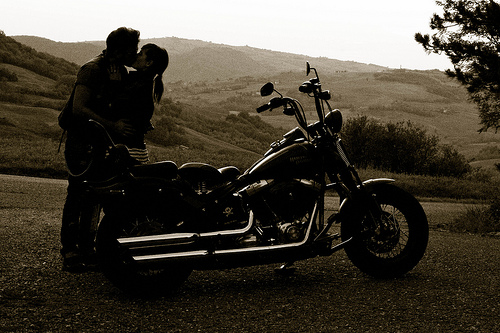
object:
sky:
[0, 0, 499, 72]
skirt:
[103, 141, 154, 169]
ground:
[0, 174, 499, 332]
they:
[58, 26, 170, 273]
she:
[93, 43, 168, 164]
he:
[60, 26, 139, 273]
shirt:
[103, 76, 155, 165]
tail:
[124, 147, 152, 166]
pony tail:
[149, 44, 170, 108]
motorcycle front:
[318, 64, 429, 279]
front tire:
[342, 181, 430, 279]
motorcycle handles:
[298, 77, 323, 92]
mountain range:
[0, 34, 392, 85]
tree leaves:
[415, 32, 427, 44]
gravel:
[276, 311, 283, 317]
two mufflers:
[118, 202, 319, 263]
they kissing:
[56, 26, 170, 271]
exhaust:
[116, 208, 256, 252]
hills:
[0, 29, 499, 203]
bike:
[68, 60, 431, 295]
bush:
[337, 114, 474, 176]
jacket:
[87, 71, 157, 134]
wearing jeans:
[62, 128, 101, 274]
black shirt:
[70, 56, 129, 140]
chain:
[87, 213, 98, 235]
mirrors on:
[259, 81, 275, 96]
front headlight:
[326, 109, 343, 134]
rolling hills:
[0, 29, 285, 175]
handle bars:
[256, 96, 288, 112]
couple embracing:
[57, 26, 169, 273]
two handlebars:
[254, 81, 322, 115]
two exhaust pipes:
[115, 202, 320, 263]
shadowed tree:
[413, 0, 500, 233]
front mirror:
[304, 62, 312, 76]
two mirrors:
[259, 61, 311, 96]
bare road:
[1, 175, 498, 332]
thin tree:
[414, 0, 498, 135]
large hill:
[9, 23, 395, 82]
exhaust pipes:
[130, 201, 319, 266]